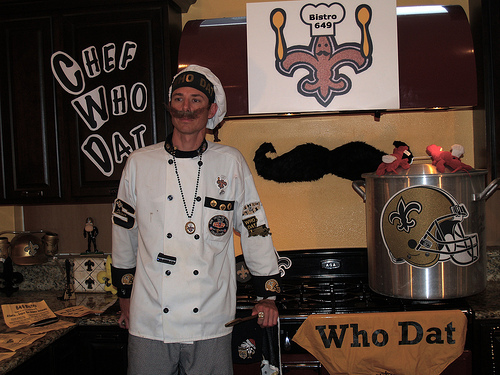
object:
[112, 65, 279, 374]
man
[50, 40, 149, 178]
writing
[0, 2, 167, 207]
cupboard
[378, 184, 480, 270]
logo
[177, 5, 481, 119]
oven hood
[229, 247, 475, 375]
stove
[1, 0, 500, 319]
kitchen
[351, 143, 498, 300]
pot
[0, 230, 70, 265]
beer cans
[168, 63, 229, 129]
hat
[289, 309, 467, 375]
towel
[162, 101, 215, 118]
fake mustache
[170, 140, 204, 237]
necklace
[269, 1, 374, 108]
image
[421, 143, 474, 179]
crawdad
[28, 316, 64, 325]
handle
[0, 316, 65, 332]
knife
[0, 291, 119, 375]
counter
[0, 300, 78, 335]
paper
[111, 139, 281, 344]
chef's jacket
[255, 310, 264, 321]
ring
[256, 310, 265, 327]
finger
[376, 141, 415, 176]
stuffed animals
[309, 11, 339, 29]
bistro 649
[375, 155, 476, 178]
lid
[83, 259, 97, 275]
spades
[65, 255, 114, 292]
decor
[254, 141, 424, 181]
mustache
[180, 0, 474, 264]
wall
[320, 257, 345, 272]
control panel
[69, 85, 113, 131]
w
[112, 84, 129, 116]
h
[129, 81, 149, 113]
o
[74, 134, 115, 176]
d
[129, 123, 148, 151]
t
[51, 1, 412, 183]
advertisements